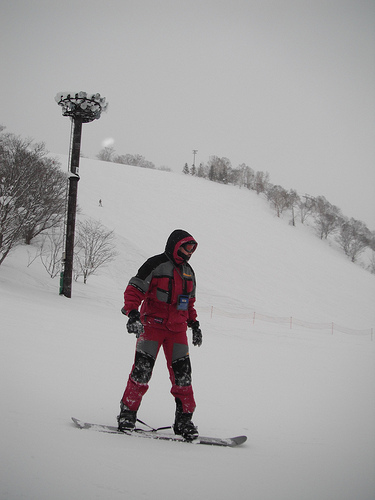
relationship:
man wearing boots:
[114, 228, 204, 444] [170, 407, 199, 442]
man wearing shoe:
[114, 228, 204, 444] [116, 414, 135, 428]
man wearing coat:
[114, 228, 204, 444] [121, 230, 200, 330]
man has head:
[114, 228, 204, 444] [165, 227, 199, 263]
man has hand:
[114, 228, 204, 444] [126, 310, 143, 328]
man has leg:
[114, 228, 204, 444] [123, 326, 160, 422]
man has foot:
[114, 228, 204, 444] [115, 410, 141, 427]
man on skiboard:
[114, 228, 204, 444] [69, 417, 248, 446]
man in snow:
[114, 228, 204, 444] [3, 146, 373, 497]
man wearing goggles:
[114, 228, 204, 444] [179, 241, 196, 254]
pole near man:
[56, 118, 81, 298] [114, 228, 204, 444]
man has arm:
[118, 228, 208, 444] [122, 257, 158, 317]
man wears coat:
[118, 228, 208, 444] [121, 230, 198, 331]